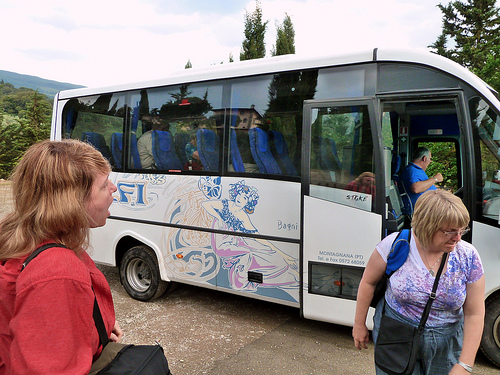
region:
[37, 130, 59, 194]
Person has light brown hair.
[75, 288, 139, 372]
Bag over person's shoulder.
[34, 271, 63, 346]
Person wearing red shirt.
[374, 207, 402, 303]
Blue strap over woman's shoulder.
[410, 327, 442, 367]
Woman wearing gray pants.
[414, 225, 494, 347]
Woman wearing v neck shirt.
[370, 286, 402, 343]
Black bag over woman's shoulder.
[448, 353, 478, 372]
Silver band around woman's wrist.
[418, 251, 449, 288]
Silver necklace on woman's neck.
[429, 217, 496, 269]
Glasses on woman's face.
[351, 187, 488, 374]
woman with short blonde hair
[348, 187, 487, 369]
woman with black shoulder bag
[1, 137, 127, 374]
woman in red shirt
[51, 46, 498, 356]
white tour bus with blue seats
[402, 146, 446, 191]
bus driver sitting in bus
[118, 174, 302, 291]
advertisement on side of bus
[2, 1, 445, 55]
cloudy sky in distance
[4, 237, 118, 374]
red shirt worn by woman on left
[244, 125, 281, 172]
blue seat back on bus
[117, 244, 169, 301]
rear tire on bus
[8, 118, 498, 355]
Two women standing near a bus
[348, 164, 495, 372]
A woman outside the bus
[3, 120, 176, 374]
A woman looking at a bus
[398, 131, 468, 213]
A man driving a bus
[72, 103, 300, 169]
Blue seats on a bus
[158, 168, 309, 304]
A woman painted on the bus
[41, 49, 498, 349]
A white bus with blue seats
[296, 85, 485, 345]
An open door on the bus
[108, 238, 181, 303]
A tire on the bus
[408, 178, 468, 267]
A woman wearing glasses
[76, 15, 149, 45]
this is the sky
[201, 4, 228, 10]
the sky is blue in color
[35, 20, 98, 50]
the sky has some clouds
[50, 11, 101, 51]
the clouds are white in color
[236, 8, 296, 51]
these are some trees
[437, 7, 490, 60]
the tree is tall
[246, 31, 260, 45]
the leaves are green in color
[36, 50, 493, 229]
this is a bus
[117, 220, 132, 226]
the bus is white in color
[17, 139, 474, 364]
these are two women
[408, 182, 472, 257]
the head of a woman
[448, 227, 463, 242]
the nose of a woman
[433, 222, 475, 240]
a pair of glasses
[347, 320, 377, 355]
the hand of a woman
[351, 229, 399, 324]
the arm of a woman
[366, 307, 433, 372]
a black purse on the woman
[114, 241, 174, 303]
a wheel on the bus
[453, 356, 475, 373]
a white bracelet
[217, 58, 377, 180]
a window on the bus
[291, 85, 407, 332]
the door of a bus